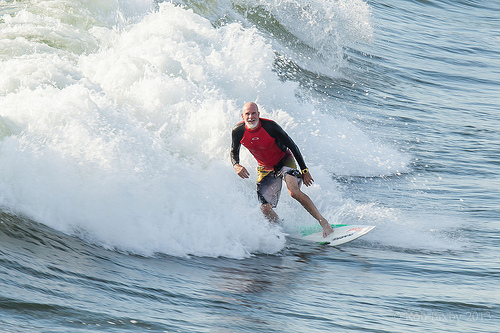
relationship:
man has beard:
[229, 100, 332, 236] [242, 117, 260, 129]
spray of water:
[74, 60, 219, 180] [382, 60, 499, 268]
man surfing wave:
[229, 100, 332, 236] [8, 0, 365, 241]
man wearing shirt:
[229, 100, 332, 236] [230, 116, 306, 171]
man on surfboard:
[229, 101, 332, 236] [272, 222, 379, 249]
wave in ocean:
[0, 0, 408, 258] [336, 1, 491, 328]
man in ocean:
[229, 101, 332, 236] [255, 5, 452, 157]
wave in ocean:
[0, 0, 408, 258] [3, 2, 497, 329]